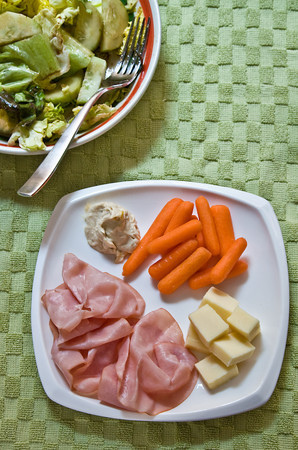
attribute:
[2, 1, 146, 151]
salad — mixed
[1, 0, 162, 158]
bowl — ceramic, red, white, round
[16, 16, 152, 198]
fork — silver, shiny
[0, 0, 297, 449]
cloth — green, checkered, white, tan, patterned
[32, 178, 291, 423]
plate — white, square, hard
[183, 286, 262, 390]
cheese — cubed, square, white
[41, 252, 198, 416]
ham — sliced, pink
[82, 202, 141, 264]
dip — yellow, gray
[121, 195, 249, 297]
carrots — peeled, orange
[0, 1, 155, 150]
ring — orange